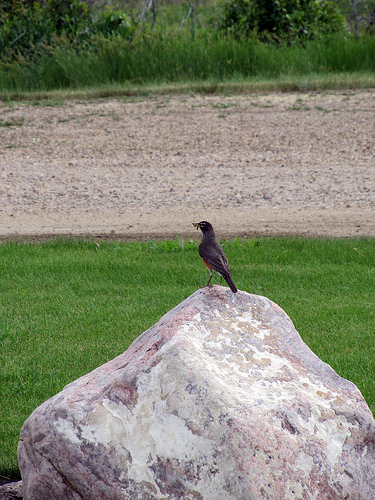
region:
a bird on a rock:
[177, 195, 271, 325]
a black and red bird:
[174, 203, 252, 311]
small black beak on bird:
[189, 217, 204, 230]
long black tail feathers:
[207, 254, 257, 317]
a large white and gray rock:
[15, 276, 356, 498]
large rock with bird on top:
[68, 204, 345, 498]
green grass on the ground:
[4, 225, 373, 438]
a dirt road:
[13, 86, 370, 270]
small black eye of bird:
[198, 218, 204, 228]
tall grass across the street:
[43, 22, 371, 76]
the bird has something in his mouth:
[142, 207, 244, 307]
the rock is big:
[76, 266, 364, 494]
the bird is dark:
[183, 204, 281, 317]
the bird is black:
[128, 203, 306, 312]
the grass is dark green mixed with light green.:
[56, 261, 160, 324]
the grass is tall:
[68, 30, 255, 79]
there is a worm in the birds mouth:
[184, 207, 244, 283]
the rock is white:
[152, 363, 259, 463]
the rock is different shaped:
[73, 301, 271, 451]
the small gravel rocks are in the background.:
[87, 116, 299, 202]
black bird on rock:
[179, 205, 251, 299]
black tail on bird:
[227, 272, 240, 289]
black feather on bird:
[210, 246, 227, 267]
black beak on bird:
[185, 212, 198, 222]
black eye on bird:
[199, 217, 203, 227]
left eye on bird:
[198, 217, 209, 234]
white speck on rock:
[177, 308, 224, 356]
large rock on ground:
[68, 279, 340, 446]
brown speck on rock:
[115, 375, 156, 422]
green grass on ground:
[32, 275, 145, 357]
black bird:
[184, 214, 236, 295]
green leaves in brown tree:
[48, 20, 81, 44]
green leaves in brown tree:
[113, 3, 149, 27]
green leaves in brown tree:
[247, 25, 286, 51]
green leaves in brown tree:
[12, 6, 49, 43]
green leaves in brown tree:
[71, 13, 142, 52]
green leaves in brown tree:
[180, 20, 210, 52]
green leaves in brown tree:
[311, 12, 347, 48]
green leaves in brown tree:
[216, 18, 238, 43]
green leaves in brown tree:
[102, 9, 146, 58]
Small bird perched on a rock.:
[0, 219, 371, 497]